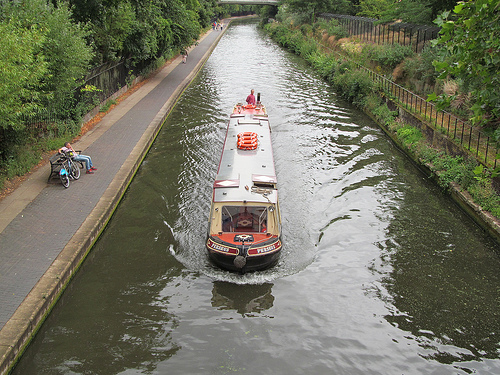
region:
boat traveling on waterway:
[192, 79, 296, 266]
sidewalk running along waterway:
[7, 10, 237, 310]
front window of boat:
[214, 205, 264, 231]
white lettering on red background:
[202, 235, 296, 250]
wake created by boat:
[175, 96, 335, 263]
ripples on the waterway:
[333, 102, 479, 364]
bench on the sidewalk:
[38, 140, 92, 187]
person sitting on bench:
[54, 144, 94, 179]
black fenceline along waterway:
[312, 9, 489, 166]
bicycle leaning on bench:
[53, 159, 79, 187]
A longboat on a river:
[202, 93, 282, 279]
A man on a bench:
[60, 140, 97, 172]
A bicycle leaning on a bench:
[55, 154, 80, 186]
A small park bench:
[50, 149, 83, 178]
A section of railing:
[318, 10, 439, 55]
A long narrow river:
[7, 11, 493, 371]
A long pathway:
[4, 19, 231, 369]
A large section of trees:
[6, 2, 203, 188]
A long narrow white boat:
[210, 90, 278, 274]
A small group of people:
[207, 19, 225, 30]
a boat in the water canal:
[193, 78, 298, 344]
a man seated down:
[46, 132, 94, 183]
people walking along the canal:
[208, 3, 223, 39]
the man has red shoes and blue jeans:
[48, 135, 101, 185]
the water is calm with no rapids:
[208, 45, 308, 330]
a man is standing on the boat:
[246, 87, 258, 114]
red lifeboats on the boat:
[233, 123, 261, 160]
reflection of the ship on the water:
[201, 268, 273, 325]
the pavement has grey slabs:
[103, 118, 137, 160]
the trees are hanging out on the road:
[78, 8, 173, 78]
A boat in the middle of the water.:
[203, 87, 283, 274]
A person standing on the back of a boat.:
[244, 88, 258, 105]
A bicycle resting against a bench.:
[57, 160, 84, 188]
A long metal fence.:
[270, 15, 497, 177]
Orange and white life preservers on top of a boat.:
[234, 128, 260, 153]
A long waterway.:
[10, 12, 499, 373]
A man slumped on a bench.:
[58, 141, 98, 175]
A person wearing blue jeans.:
[60, 142, 97, 173]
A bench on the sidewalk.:
[48, 148, 98, 180]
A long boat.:
[205, 98, 284, 273]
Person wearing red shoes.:
[87, 163, 98, 177]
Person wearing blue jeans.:
[77, 153, 98, 170]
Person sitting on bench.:
[51, 142, 84, 180]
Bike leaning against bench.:
[51, 151, 91, 190]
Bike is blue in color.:
[44, 143, 108, 206]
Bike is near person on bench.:
[53, 139, 113, 219]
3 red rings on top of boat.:
[235, 123, 272, 163]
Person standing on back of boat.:
[241, 78, 264, 113]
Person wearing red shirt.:
[243, 86, 256, 111]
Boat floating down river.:
[216, 105, 294, 332]